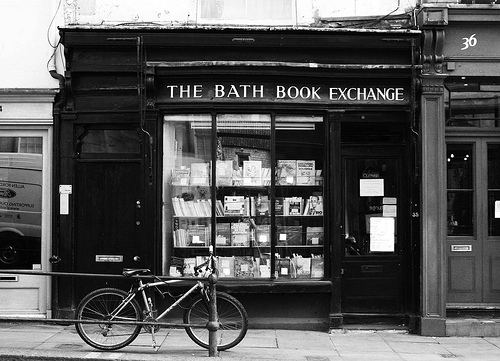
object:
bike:
[74, 243, 248, 349]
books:
[171, 161, 190, 179]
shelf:
[169, 182, 324, 278]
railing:
[0, 268, 218, 358]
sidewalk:
[0, 320, 498, 361]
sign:
[369, 216, 394, 252]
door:
[341, 143, 406, 312]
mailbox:
[95, 254, 123, 262]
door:
[77, 161, 145, 314]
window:
[0, 136, 41, 269]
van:
[0, 152, 41, 269]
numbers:
[460, 33, 477, 52]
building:
[420, 3, 500, 335]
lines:
[46, 1, 63, 70]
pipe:
[48, 70, 64, 319]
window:
[163, 115, 325, 282]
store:
[49, 26, 422, 330]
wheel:
[183, 290, 247, 351]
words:
[166, 83, 403, 102]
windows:
[345, 158, 397, 255]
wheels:
[74, 287, 142, 351]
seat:
[123, 267, 150, 277]